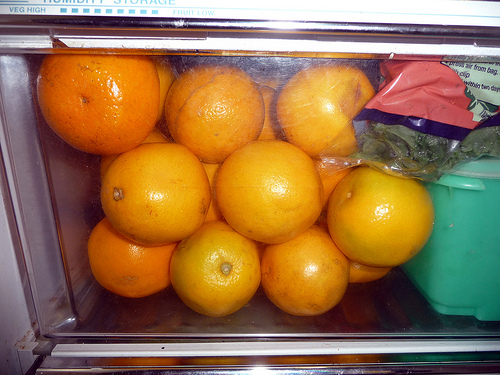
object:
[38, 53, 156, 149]
fruit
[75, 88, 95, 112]
spot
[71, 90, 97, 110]
spot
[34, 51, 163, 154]
fruit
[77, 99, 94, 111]
spot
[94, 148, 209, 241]
fruit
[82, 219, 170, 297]
fruit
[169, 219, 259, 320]
fruit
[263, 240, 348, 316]
fruit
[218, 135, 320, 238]
fruit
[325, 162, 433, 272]
fruit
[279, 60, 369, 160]
fruit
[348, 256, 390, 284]
fruit